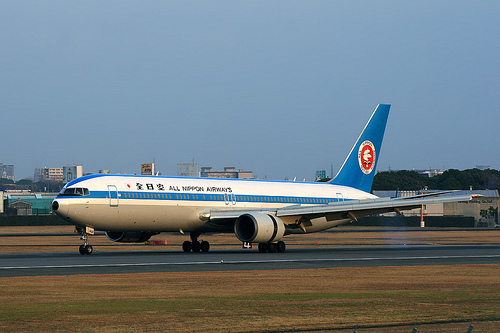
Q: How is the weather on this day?
A: It is cloudless.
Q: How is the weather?
A: It is cloudless.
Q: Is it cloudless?
A: Yes, it is cloudless.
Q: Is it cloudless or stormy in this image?
A: It is cloudless.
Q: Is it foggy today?
A: No, it is cloudless.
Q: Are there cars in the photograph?
A: No, there are no cars.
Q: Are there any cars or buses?
A: No, there are no cars or buses.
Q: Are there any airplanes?
A: Yes, there is an airplane.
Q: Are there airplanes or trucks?
A: Yes, there is an airplane.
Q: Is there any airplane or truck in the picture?
A: Yes, there is an airplane.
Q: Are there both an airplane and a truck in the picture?
A: No, there is an airplane but no trucks.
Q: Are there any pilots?
A: No, there are no pilots.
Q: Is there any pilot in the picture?
A: No, there are no pilots.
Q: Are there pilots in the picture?
A: No, there are no pilots.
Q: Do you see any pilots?
A: No, there are no pilots.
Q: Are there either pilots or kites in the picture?
A: No, there are no pilots or kites.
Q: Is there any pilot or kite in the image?
A: No, there are no pilots or kites.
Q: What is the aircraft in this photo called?
A: The aircraft is an airplane.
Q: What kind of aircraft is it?
A: The aircraft is an airplane.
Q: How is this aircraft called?
A: This is an airplane.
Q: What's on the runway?
A: The plane is on the runway.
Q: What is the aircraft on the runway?
A: The aircraft is an airplane.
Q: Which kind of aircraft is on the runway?
A: The aircraft is an airplane.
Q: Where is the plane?
A: The plane is on the runway.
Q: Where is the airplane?
A: The plane is on the runway.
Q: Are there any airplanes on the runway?
A: Yes, there is an airplane on the runway.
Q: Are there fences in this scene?
A: No, there are no fences.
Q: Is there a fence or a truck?
A: No, there are no fences or trucks.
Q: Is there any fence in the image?
A: No, there are no fences.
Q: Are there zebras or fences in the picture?
A: No, there are no fences or zebras.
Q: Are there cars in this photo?
A: No, there are no cars.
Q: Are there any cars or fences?
A: No, there are no cars or fences.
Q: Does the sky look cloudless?
A: Yes, the sky is cloudless.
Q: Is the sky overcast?
A: No, the sky is cloudless.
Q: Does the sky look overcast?
A: No, the sky is cloudless.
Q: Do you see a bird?
A: No, there are no birds.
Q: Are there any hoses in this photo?
A: No, there are no hoses.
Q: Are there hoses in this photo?
A: No, there are no hoses.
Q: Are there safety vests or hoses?
A: No, there are no hoses or safety vests.